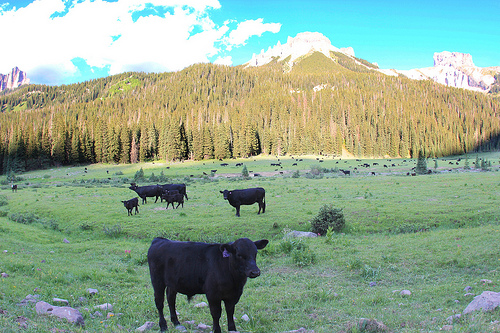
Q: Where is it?
A: This is at the field.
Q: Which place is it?
A: It is a field.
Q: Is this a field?
A: Yes, it is a field.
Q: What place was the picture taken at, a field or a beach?
A: It was taken at a field.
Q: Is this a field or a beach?
A: It is a field.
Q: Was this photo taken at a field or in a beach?
A: It was taken at a field.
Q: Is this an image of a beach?
A: No, the picture is showing a field.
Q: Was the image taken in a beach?
A: No, the picture was taken in a field.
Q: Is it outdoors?
A: Yes, it is outdoors.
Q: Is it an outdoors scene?
A: Yes, it is outdoors.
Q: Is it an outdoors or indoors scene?
A: It is outdoors.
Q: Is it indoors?
A: No, it is outdoors.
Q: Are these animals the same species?
A: Yes, all the animals are cows.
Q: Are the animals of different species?
A: No, all the animals are cows.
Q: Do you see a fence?
A: No, there are no fences.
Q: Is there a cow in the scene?
A: Yes, there is a cow.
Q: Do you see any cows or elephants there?
A: Yes, there is a cow.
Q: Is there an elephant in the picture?
A: No, there are no elephants.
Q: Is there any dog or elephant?
A: No, there are no elephants or dogs.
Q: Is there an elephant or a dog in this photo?
A: No, there are no elephants or dogs.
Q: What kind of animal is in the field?
A: The animal is a cow.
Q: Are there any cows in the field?
A: Yes, there is a cow in the field.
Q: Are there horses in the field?
A: No, there is a cow in the field.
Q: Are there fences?
A: No, there are no fences.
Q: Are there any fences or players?
A: No, there are no fences or players.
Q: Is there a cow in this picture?
A: Yes, there is a cow.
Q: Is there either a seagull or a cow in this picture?
A: Yes, there is a cow.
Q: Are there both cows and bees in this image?
A: No, there is a cow but no bees.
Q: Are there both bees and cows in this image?
A: No, there is a cow but no bees.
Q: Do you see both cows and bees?
A: No, there is a cow but no bees.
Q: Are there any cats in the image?
A: No, there are no cats.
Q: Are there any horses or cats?
A: No, there are no cats or horses.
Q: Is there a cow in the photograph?
A: Yes, there are cows.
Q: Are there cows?
A: Yes, there are cows.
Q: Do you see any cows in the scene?
A: Yes, there are cows.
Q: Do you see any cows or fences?
A: Yes, there are cows.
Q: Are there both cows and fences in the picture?
A: No, there are cows but no fences.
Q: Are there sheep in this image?
A: No, there are no sheep.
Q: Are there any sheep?
A: No, there are no sheep.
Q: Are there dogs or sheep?
A: No, there are no sheep or dogs.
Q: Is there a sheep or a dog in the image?
A: No, there are no sheep or dogs.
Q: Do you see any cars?
A: No, there are no cars.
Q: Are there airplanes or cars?
A: No, there are no cars or airplanes.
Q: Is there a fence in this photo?
A: No, there are no fences.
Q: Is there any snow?
A: Yes, there is snow.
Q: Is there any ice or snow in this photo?
A: Yes, there is snow.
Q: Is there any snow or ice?
A: Yes, there is snow.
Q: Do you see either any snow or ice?
A: Yes, there is snow.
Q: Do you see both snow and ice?
A: No, there is snow but no ice.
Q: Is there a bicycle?
A: No, there are no bicycles.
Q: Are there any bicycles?
A: No, there are no bicycles.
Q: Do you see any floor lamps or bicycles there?
A: No, there are no bicycles or floor lamps.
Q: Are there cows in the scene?
A: Yes, there is a cow.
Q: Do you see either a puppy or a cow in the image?
A: Yes, there is a cow.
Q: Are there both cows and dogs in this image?
A: No, there is a cow but no dogs.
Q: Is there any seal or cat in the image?
A: No, there are no cats or seals.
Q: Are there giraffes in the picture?
A: No, there are no giraffes.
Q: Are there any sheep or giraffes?
A: No, there are no giraffes or sheep.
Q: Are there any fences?
A: No, there are no fences.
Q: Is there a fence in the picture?
A: No, there are no fences.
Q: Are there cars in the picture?
A: No, there are no cars.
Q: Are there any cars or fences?
A: No, there are no cars or fences.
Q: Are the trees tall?
A: Yes, the trees are tall.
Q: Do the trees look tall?
A: Yes, the trees are tall.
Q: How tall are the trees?
A: The trees are tall.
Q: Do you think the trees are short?
A: No, the trees are tall.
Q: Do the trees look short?
A: No, the trees are tall.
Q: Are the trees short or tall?
A: The trees are tall.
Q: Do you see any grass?
A: Yes, there is grass.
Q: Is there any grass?
A: Yes, there is grass.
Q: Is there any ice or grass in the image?
A: Yes, there is grass.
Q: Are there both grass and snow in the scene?
A: Yes, there are both grass and snow.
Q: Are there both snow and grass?
A: Yes, there are both grass and snow.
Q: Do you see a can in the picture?
A: No, there are no cans.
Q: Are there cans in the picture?
A: No, there are no cans.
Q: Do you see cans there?
A: No, there are no cans.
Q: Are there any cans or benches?
A: No, there are no cans or benches.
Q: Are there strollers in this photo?
A: No, there are no strollers.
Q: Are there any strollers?
A: No, there are no strollers.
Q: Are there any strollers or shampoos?
A: No, there are no strollers or shampoos.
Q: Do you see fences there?
A: No, there are no fences.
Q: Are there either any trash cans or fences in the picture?
A: No, there are no fences or trash cans.